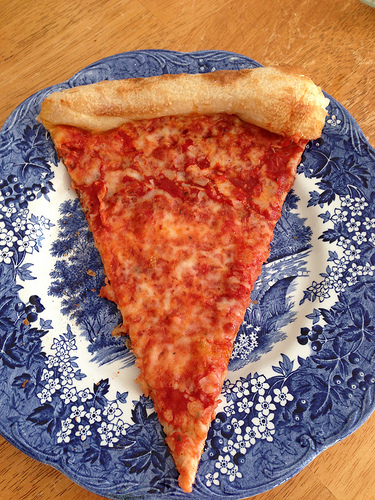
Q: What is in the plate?
A: A pizza slice.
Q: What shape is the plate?
A: A circle.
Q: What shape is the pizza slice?
A: Triangle.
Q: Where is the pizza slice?
A: In the plate.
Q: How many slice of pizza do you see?
A: 1.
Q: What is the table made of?
A: Wood.